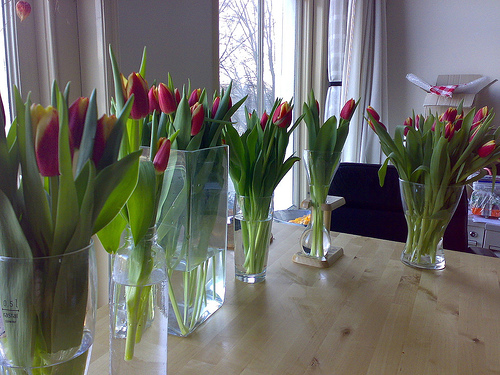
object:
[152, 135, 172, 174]
flowers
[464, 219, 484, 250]
cabinet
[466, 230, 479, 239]
lock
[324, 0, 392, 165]
drape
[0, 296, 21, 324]
measuring marker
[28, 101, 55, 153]
yellow center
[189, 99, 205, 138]
pink tulip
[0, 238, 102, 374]
vase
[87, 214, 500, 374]
table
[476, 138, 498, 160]
flowers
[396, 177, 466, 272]
vase